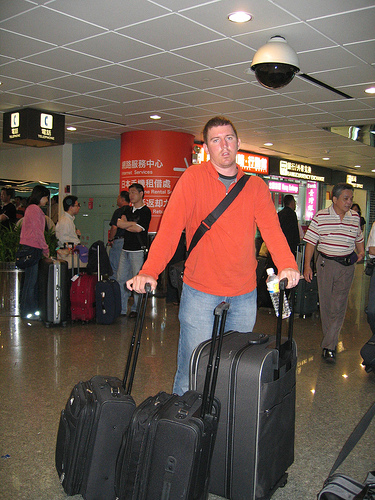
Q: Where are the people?
A: The airport.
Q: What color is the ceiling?
A: White.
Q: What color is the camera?
A: Black.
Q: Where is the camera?
A: On ceiling.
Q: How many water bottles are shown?
A: One.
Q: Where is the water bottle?
A: Man's hands.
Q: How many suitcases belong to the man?
A: Three.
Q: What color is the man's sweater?
A: Orange.